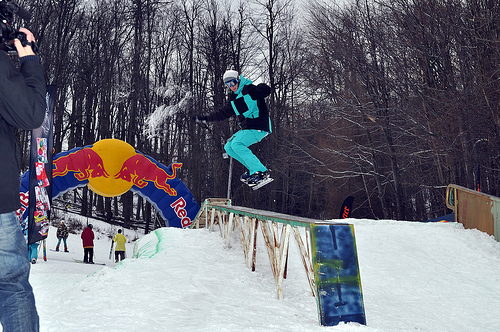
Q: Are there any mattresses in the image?
A: No, there are no mattresses.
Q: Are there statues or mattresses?
A: No, there are no mattresses or statues.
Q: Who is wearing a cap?
A: The man is wearing a cap.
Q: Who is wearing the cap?
A: The man is wearing a cap.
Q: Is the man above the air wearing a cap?
A: Yes, the man is wearing a cap.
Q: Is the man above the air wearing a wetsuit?
A: No, the man is wearing a cap.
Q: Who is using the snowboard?
A: The man is using the snowboard.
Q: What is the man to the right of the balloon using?
A: The man is using a snowboard.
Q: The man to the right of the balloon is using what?
A: The man is using a snowboard.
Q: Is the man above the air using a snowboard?
A: Yes, the man is using a snowboard.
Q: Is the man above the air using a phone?
A: No, the man is using a snowboard.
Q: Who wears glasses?
A: The man wears glasses.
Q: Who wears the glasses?
A: The man wears glasses.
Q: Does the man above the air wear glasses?
A: Yes, the man wears glasses.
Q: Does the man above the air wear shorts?
A: No, the man wears glasses.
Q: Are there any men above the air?
A: Yes, there is a man above the air.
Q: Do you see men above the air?
A: Yes, there is a man above the air.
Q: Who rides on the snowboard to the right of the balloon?
A: The man rides on the snowboard.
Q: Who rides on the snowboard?
A: The man rides on the snowboard.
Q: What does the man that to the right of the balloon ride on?
A: The man rides on the snow board.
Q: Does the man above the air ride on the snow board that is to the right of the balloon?
A: Yes, the man rides on the snowboard.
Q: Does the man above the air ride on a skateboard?
A: No, the man rides on the snowboard.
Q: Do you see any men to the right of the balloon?
A: Yes, there is a man to the right of the balloon.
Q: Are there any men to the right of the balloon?
A: Yes, there is a man to the right of the balloon.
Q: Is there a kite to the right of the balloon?
A: No, there is a man to the right of the balloon.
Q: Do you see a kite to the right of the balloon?
A: No, there is a man to the right of the balloon.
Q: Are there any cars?
A: No, there are no cars.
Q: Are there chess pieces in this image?
A: No, there are no chess pieces.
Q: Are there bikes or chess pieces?
A: No, there are no chess pieces or bikes.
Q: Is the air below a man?
A: Yes, the air is below a man.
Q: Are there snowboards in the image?
A: Yes, there is a snowboard.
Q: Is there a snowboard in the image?
A: Yes, there is a snowboard.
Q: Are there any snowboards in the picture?
A: Yes, there is a snowboard.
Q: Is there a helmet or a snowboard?
A: Yes, there is a snowboard.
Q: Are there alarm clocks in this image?
A: No, there are no alarm clocks.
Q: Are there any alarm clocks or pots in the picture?
A: No, there are no alarm clocks or pots.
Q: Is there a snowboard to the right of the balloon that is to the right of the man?
A: Yes, there is a snowboard to the right of the balloon.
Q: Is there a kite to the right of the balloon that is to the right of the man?
A: No, there is a snowboard to the right of the balloon.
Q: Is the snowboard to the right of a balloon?
A: Yes, the snowboard is to the right of a balloon.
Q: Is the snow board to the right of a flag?
A: No, the snow board is to the right of a balloon.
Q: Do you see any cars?
A: No, there are no cars.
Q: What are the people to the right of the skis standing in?
A: The people are standing in the snow.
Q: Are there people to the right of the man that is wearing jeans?
A: Yes, there are people to the right of the man.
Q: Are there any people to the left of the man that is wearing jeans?
A: No, the people are to the right of the man.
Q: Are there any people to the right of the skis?
A: Yes, there are people to the right of the skis.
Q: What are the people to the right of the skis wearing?
A: The people are wearing a coat.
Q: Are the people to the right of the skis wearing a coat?
A: Yes, the people are wearing a coat.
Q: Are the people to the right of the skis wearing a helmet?
A: No, the people are wearing a coat.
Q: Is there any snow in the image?
A: Yes, there is snow.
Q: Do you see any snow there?
A: Yes, there is snow.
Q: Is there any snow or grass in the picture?
A: Yes, there is snow.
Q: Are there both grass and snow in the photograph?
A: No, there is snow but no grass.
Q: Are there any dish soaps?
A: No, there are no dish soaps.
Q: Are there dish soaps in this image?
A: No, there are no dish soaps.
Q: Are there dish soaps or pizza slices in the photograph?
A: No, there are no dish soaps or pizza slices.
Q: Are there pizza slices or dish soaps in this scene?
A: No, there are no dish soaps or pizza slices.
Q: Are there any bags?
A: No, there are no bags.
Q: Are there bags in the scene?
A: No, there are no bags.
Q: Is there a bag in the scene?
A: No, there are no bags.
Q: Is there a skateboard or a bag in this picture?
A: No, there are no bags or skateboards.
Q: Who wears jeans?
A: The man wears jeans.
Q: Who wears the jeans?
A: The man wears jeans.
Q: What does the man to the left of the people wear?
A: The man wears jeans.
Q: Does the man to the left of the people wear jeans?
A: Yes, the man wears jeans.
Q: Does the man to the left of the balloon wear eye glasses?
A: No, the man wears jeans.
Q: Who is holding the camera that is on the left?
A: The man is holding the camera.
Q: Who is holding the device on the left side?
A: The man is holding the camera.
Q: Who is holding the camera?
A: The man is holding the camera.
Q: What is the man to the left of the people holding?
A: The man is holding the camera.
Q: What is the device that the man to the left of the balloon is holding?
A: The device is a camera.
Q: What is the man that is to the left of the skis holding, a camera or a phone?
A: The man is holding a camera.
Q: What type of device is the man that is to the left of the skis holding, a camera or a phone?
A: The man is holding a camera.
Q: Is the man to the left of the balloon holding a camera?
A: Yes, the man is holding a camera.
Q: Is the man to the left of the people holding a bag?
A: No, the man is holding a camera.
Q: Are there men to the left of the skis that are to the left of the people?
A: Yes, there is a man to the left of the skis.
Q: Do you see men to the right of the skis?
A: No, the man is to the left of the skis.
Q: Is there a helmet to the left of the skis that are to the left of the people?
A: No, there is a man to the left of the skis.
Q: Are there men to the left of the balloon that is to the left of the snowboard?
A: Yes, there is a man to the left of the balloon.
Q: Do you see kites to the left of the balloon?
A: No, there is a man to the left of the balloon.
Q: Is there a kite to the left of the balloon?
A: No, there is a man to the left of the balloon.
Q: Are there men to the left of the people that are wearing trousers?
A: Yes, there is a man to the left of the people.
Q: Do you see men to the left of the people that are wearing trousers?
A: Yes, there is a man to the left of the people.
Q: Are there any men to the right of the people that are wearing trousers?
A: No, the man is to the left of the people.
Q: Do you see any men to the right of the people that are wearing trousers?
A: No, the man is to the left of the people.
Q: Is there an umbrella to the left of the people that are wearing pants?
A: No, there is a man to the left of the people.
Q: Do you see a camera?
A: Yes, there is a camera.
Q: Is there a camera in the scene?
A: Yes, there is a camera.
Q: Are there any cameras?
A: Yes, there is a camera.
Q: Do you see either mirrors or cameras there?
A: Yes, there is a camera.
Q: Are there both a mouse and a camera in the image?
A: No, there is a camera but no computer mice.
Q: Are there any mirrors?
A: No, there are no mirrors.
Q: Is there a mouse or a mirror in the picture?
A: No, there are no mirrors or computer mice.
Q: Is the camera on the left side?
A: Yes, the camera is on the left of the image.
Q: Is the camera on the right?
A: No, the camera is on the left of the image.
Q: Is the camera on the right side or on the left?
A: The camera is on the left of the image.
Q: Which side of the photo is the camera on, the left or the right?
A: The camera is on the left of the image.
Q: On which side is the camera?
A: The camera is on the left of the image.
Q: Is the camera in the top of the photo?
A: Yes, the camera is in the top of the image.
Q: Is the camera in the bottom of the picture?
A: No, the camera is in the top of the image.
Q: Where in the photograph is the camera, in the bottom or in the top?
A: The camera is in the top of the image.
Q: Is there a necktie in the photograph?
A: No, there are no ties.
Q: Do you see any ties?
A: No, there are no ties.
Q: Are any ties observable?
A: No, there are no ties.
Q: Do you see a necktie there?
A: No, there are no ties.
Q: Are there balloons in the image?
A: Yes, there is a balloon.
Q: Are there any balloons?
A: Yes, there is a balloon.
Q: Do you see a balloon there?
A: Yes, there is a balloon.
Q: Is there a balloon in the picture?
A: Yes, there is a balloon.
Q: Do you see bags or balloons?
A: Yes, there is a balloon.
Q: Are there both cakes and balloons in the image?
A: No, there is a balloon but no cakes.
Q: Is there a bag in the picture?
A: No, there are no bags.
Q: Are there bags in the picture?
A: No, there are no bags.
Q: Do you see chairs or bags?
A: No, there are no bags or chairs.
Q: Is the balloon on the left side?
A: Yes, the balloon is on the left of the image.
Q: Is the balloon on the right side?
A: No, the balloon is on the left of the image.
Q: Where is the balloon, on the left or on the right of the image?
A: The balloon is on the left of the image.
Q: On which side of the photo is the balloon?
A: The balloon is on the left of the image.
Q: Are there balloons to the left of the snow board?
A: Yes, there is a balloon to the left of the snow board.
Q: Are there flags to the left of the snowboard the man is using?
A: No, there is a balloon to the left of the snowboard.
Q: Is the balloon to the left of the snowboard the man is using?
A: Yes, the balloon is to the left of the snow board.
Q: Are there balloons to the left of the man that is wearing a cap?
A: Yes, there is a balloon to the left of the man.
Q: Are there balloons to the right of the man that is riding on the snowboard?
A: No, the balloon is to the left of the man.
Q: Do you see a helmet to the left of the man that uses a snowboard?
A: No, there is a balloon to the left of the man.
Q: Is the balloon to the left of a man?
A: Yes, the balloon is to the left of a man.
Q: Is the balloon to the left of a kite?
A: No, the balloon is to the left of a man.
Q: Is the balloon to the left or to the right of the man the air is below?
A: The balloon is to the left of the man.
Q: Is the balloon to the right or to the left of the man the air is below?
A: The balloon is to the left of the man.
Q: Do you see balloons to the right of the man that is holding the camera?
A: Yes, there is a balloon to the right of the man.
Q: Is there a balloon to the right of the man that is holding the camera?
A: Yes, there is a balloon to the right of the man.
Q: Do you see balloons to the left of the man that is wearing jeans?
A: No, the balloon is to the right of the man.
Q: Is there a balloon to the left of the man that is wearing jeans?
A: No, the balloon is to the right of the man.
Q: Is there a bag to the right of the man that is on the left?
A: No, there is a balloon to the right of the man.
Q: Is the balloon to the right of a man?
A: Yes, the balloon is to the right of a man.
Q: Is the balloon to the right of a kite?
A: No, the balloon is to the right of a man.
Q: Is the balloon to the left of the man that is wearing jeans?
A: No, the balloon is to the right of the man.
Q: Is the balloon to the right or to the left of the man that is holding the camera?
A: The balloon is to the right of the man.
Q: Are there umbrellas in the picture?
A: No, there are no umbrellas.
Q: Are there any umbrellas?
A: No, there are no umbrellas.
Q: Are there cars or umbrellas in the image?
A: No, there are no umbrellas or cars.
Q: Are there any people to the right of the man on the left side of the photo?
A: Yes, there are people to the right of the man.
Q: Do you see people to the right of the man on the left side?
A: Yes, there are people to the right of the man.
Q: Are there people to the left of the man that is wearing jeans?
A: No, the people are to the right of the man.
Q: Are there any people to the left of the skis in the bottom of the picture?
A: Yes, there are people to the left of the skis.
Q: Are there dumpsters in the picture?
A: No, there are no dumpsters.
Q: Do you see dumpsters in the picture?
A: No, there are no dumpsters.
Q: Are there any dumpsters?
A: No, there are no dumpsters.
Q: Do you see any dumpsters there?
A: No, there are no dumpsters.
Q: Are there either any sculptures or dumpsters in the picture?
A: No, there are no dumpsters or sculptures.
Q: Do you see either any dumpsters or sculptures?
A: No, there are no dumpsters or sculptures.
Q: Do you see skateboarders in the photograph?
A: Yes, there is a skateboarder.